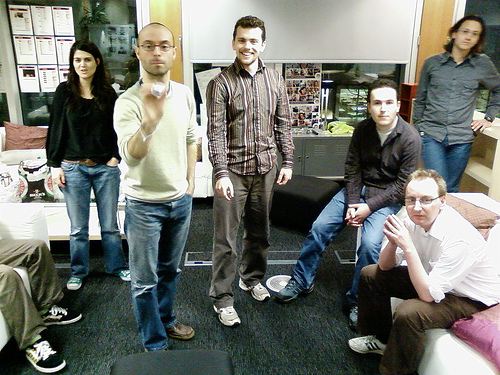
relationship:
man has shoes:
[110, 19, 200, 352] [144, 316, 195, 347]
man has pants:
[189, 10, 307, 180] [207, 157, 277, 294]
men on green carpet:
[132, 9, 499, 374] [25, 203, 377, 373]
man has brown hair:
[418, 20, 475, 174] [434, 12, 486, 67]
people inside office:
[58, 8, 498, 337] [0, 0, 491, 370]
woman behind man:
[41, 36, 135, 208] [111, 19, 225, 226]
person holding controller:
[110, 18, 197, 353] [151, 81, 165, 101]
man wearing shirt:
[256, 67, 444, 333] [205, 56, 296, 175]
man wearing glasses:
[342, 165, 498, 373] [401, 193, 442, 206]